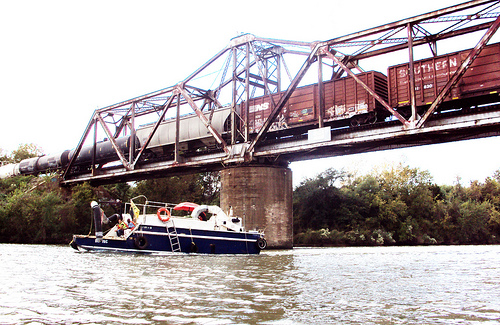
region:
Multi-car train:
[7, 79, 485, 174]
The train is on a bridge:
[20, 42, 495, 148]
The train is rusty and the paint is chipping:
[11, 40, 496, 165]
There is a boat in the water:
[61, 166, 277, 252]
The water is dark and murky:
[6, 263, 478, 324]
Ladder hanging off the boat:
[157, 218, 192, 258]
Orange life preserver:
[154, 204, 171, 221]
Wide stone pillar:
[224, 163, 305, 243]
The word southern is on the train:
[390, 55, 462, 72]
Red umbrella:
[170, 190, 205, 213]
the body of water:
[0, 241, 497, 324]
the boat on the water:
[67, 194, 266, 256]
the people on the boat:
[115, 217, 135, 238]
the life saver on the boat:
[156, 207, 171, 223]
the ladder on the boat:
[165, 217, 182, 254]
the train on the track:
[4, 43, 498, 175]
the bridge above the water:
[56, 103, 497, 186]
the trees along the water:
[0, 144, 498, 244]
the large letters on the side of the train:
[398, 58, 456, 80]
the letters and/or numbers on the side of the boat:
[93, 237, 108, 244]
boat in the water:
[71, 183, 283, 277]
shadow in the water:
[201, 251, 301, 309]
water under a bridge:
[337, 251, 464, 305]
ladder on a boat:
[161, 223, 186, 260]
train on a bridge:
[7, 0, 498, 180]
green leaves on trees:
[302, 174, 494, 223]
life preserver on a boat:
[149, 203, 171, 225]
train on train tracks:
[1, 148, 108, 178]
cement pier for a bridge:
[217, 171, 306, 261]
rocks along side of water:
[303, 225, 438, 247]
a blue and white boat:
[73, 201, 274, 252]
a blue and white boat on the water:
[73, 199, 269, 258]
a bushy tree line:
[316, 174, 496, 245]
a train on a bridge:
[50, 41, 499, 163]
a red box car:
[391, 43, 498, 117]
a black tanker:
[68, 132, 132, 182]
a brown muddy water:
[3, 261, 483, 319]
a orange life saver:
[157, 208, 173, 222]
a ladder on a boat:
[164, 218, 181, 256]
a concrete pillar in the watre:
[244, 172, 305, 256]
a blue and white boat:
[66, 177, 304, 277]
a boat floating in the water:
[76, 172, 305, 272]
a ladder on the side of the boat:
[157, 193, 195, 254]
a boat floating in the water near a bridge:
[51, 179, 316, 280]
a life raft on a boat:
[140, 192, 195, 237]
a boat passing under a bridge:
[61, 159, 321, 280]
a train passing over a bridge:
[54, 2, 466, 199]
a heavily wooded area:
[305, 166, 497, 248]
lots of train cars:
[28, 3, 462, 173]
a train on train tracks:
[39, 70, 356, 188]